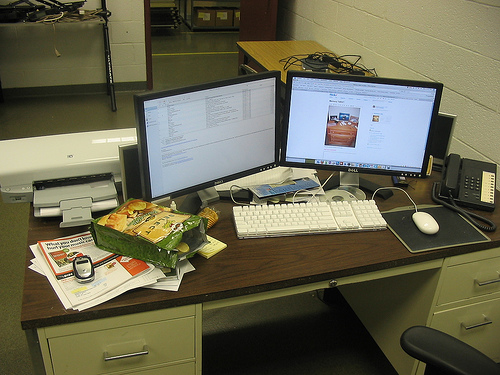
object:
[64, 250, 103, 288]
phone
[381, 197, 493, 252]
mouse pad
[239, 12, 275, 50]
door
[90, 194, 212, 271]
chips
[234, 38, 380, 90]
table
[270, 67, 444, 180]
computer monitor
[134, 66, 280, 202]
computer monitor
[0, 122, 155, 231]
printe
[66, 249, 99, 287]
flip phone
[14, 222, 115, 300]
pile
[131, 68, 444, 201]
monitor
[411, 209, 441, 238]
mouse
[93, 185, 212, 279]
crackers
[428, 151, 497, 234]
phone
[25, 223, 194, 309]
papers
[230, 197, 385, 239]
keyboard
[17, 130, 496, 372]
desk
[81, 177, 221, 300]
bag